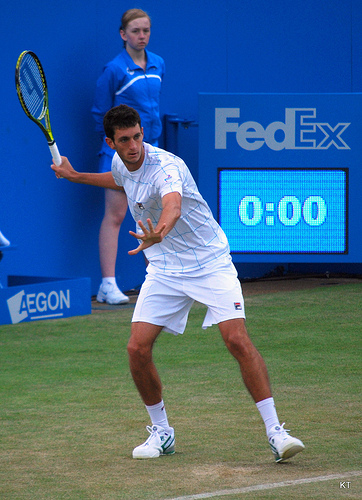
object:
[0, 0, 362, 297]
wall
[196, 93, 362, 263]
sign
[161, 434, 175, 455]
stripes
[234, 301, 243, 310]
logo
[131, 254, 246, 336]
shorts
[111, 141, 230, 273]
shirt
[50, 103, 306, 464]
man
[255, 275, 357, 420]
grass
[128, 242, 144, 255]
fingers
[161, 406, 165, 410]
label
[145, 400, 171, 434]
white sock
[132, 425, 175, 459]
shoe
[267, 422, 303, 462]
shoe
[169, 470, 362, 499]
line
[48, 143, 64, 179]
white grip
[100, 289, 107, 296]
nike logo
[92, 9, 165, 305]
woman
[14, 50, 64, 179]
racket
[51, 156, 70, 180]
hand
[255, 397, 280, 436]
sock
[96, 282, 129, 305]
shoe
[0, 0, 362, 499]
tennis court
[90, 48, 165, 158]
blue jacket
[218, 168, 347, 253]
clock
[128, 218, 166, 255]
hand